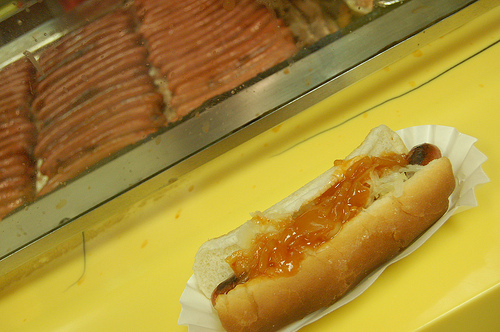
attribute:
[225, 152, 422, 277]
onions — grilled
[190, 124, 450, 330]
hotdog — grilled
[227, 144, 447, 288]
hot dog — grilled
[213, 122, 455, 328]
hot dog — black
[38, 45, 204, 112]
hot dogs — grilled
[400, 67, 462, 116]
counter — yellow, cracked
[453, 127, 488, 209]
paper wrap — white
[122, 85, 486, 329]
tray — white